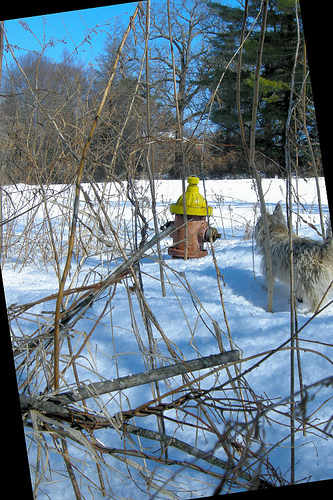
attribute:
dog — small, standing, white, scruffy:
[256, 200, 330, 317]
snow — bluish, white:
[1, 175, 331, 499]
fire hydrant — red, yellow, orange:
[160, 175, 220, 263]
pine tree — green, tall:
[194, 0, 318, 179]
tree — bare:
[123, 0, 230, 180]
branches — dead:
[1, 0, 331, 500]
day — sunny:
[0, 0, 332, 499]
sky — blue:
[1, 0, 332, 158]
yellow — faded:
[170, 176, 212, 216]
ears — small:
[259, 199, 284, 217]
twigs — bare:
[0, 0, 331, 497]